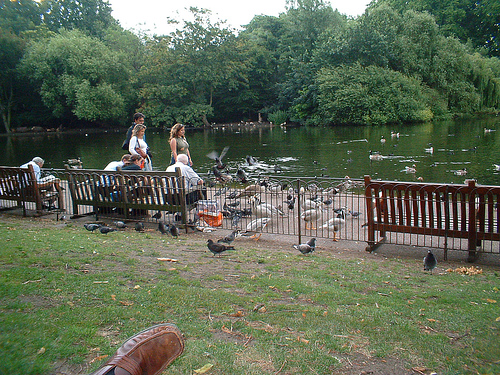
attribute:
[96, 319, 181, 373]
shoe — brown 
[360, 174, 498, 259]
bench — wooden 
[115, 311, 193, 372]
shoe — brown, leather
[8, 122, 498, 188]
lake — large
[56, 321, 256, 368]
shoe — leather, brown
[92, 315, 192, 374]
shoe — brown 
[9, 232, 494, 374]
green — green 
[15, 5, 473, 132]
trees — green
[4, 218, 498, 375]
ground — brown 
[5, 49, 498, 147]
trees — large